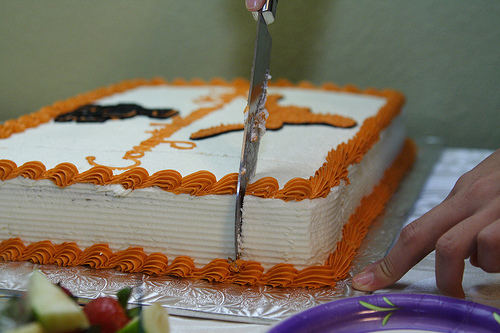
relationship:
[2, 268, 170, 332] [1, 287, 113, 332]
fruit in a bowl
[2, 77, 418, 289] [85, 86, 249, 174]
cake has writing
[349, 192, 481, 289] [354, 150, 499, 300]
middle finger of a hand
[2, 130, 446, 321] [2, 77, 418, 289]
tray for a cake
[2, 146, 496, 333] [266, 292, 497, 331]
table has a plate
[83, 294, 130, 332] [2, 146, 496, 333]
strawberry on table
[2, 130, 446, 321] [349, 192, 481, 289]
tray being held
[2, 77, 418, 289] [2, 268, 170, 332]
cake by fruit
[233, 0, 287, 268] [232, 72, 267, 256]
knife has icing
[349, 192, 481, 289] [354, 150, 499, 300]
middle finger of a person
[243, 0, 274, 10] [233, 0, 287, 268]
finger on knife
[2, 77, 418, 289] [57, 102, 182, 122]
cake has black image